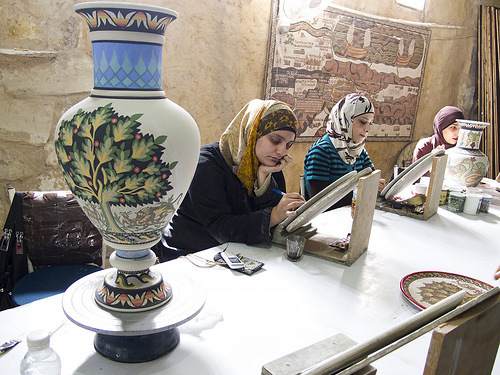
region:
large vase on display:
[48, 3, 210, 366]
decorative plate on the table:
[398, 268, 498, 322]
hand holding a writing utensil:
[263, 183, 301, 218]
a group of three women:
[158, 77, 480, 269]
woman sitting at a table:
[160, 95, 311, 258]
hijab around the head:
[323, 85, 376, 172]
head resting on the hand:
[248, 106, 298, 199]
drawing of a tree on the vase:
[49, 100, 186, 256]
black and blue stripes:
[300, 135, 382, 200]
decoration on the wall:
[259, 3, 435, 159]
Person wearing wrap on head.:
[233, 100, 280, 159]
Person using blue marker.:
[272, 181, 304, 220]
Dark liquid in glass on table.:
[281, 240, 316, 274]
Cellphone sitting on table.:
[222, 247, 245, 282]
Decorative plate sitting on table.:
[402, 269, 492, 329]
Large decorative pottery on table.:
[61, 264, 189, 316]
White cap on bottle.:
[20, 326, 68, 356]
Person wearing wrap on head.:
[332, 91, 374, 148]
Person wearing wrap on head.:
[422, 103, 446, 131]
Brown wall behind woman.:
[192, 65, 219, 92]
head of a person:
[236, 93, 301, 167]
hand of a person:
[257, 145, 293, 175]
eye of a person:
[269, 129, 283, 149]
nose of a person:
[279, 143, 286, 155]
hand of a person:
[262, 182, 296, 218]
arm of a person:
[187, 189, 255, 251]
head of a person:
[333, 92, 371, 147]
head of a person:
[434, 99, 471, 147]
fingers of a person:
[277, 187, 306, 214]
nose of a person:
[360, 120, 371, 135]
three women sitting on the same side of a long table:
[2, 92, 497, 374]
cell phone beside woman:
[163, 96, 306, 273]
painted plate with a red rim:
[398, 270, 493, 315]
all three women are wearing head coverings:
[217, 92, 464, 192]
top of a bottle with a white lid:
[18, 331, 60, 374]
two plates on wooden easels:
[271, 144, 447, 265]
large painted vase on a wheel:
[52, 1, 204, 361]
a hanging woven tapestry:
[262, 1, 431, 143]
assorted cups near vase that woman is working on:
[411, 106, 492, 214]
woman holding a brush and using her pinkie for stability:
[267, 184, 305, 218]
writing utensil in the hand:
[263, 185, 305, 229]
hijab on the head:
[319, 80, 382, 170]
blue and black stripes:
[296, 132, 387, 194]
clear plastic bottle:
[9, 328, 70, 373]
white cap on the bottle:
[26, 328, 55, 351]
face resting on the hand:
[245, 113, 302, 193]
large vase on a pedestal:
[58, 0, 212, 363]